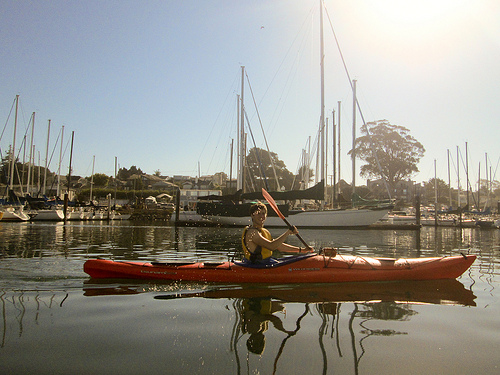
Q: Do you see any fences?
A: No, there are no fences.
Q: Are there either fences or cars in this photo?
A: No, there are no fences or cars.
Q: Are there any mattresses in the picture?
A: No, there are no mattresses.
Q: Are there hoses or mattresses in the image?
A: No, there are no mattresses or hoses.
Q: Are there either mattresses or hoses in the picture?
A: No, there are no mattresses or hoses.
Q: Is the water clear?
A: Yes, the water is clear.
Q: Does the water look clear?
A: Yes, the water is clear.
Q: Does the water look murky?
A: No, the water is clear.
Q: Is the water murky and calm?
A: No, the water is calm but clear.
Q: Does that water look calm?
A: Yes, the water is calm.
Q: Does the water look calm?
A: Yes, the water is calm.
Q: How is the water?
A: The water is calm.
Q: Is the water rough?
A: No, the water is calm.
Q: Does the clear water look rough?
A: No, the water is calm.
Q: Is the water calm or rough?
A: The water is calm.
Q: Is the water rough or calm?
A: The water is calm.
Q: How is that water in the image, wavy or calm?
A: The water is calm.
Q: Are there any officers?
A: No, there are no officers.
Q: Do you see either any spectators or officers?
A: No, there are no officers or spectators.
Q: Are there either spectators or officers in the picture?
A: No, there are no officers or spectators.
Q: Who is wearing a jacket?
A: The man is wearing a jacket.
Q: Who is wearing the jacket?
A: The man is wearing a jacket.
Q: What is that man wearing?
A: The man is wearing a jacket.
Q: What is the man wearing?
A: The man is wearing a jacket.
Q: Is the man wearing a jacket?
A: Yes, the man is wearing a jacket.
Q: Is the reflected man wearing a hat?
A: No, the man is wearing a jacket.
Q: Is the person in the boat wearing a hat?
A: No, the man is wearing a jacket.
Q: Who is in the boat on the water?
A: The man is in the boat.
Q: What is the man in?
A: The man is in the boat.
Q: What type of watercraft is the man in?
A: The man is in the boat.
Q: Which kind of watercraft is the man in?
A: The man is in the boat.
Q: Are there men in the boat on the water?
A: Yes, there is a man in the boat.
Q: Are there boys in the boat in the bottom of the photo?
A: No, there is a man in the boat.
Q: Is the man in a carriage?
A: No, the man is in the boat.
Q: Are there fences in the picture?
A: No, there are no fences.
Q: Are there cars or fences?
A: No, there are no fences or cars.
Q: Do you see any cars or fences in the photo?
A: No, there are no fences or cars.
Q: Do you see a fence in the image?
A: No, there are no fences.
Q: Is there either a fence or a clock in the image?
A: No, there are no fences or clocks.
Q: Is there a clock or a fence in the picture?
A: No, there are no fences or clocks.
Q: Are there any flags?
A: No, there are no flags.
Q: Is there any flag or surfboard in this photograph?
A: No, there are no flags or surfboards.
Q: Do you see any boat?
A: Yes, there is a boat.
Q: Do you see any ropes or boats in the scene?
A: Yes, there is a boat.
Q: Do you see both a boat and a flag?
A: No, there is a boat but no flags.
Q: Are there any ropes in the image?
A: No, there are no ropes.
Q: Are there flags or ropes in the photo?
A: No, there are no ropes or flags.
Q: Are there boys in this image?
A: No, there are no boys.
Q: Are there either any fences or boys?
A: No, there are no boys or fences.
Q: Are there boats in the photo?
A: Yes, there is a boat.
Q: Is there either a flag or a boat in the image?
A: Yes, there is a boat.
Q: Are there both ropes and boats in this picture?
A: No, there is a boat but no ropes.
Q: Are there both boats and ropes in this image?
A: No, there is a boat but no ropes.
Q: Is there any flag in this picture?
A: No, there are no flags.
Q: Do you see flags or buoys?
A: No, there are no flags or buoys.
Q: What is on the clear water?
A: The boat is on the water.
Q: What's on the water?
A: The boat is on the water.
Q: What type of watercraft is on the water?
A: The watercraft is a boat.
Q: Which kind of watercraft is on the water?
A: The watercraft is a boat.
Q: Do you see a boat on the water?
A: Yes, there is a boat on the water.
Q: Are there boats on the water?
A: Yes, there is a boat on the water.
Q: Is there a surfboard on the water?
A: No, there is a boat on the water.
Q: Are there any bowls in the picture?
A: No, there are no bowls.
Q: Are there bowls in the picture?
A: No, there are no bowls.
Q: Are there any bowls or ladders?
A: No, there are no bowls or ladders.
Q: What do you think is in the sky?
A: The sun is in the sky.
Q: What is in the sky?
A: The sun is in the sky.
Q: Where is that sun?
A: The sun is in the sky.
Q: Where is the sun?
A: The sun is in the sky.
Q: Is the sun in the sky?
A: Yes, the sun is in the sky.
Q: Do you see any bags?
A: No, there are no bags.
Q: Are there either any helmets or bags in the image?
A: No, there are no bags or helmets.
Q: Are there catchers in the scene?
A: No, there are no catchers.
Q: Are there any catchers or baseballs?
A: No, there are no catchers or baseballs.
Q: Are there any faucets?
A: No, there are no faucets.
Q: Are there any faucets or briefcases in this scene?
A: No, there are no faucets or briefcases.